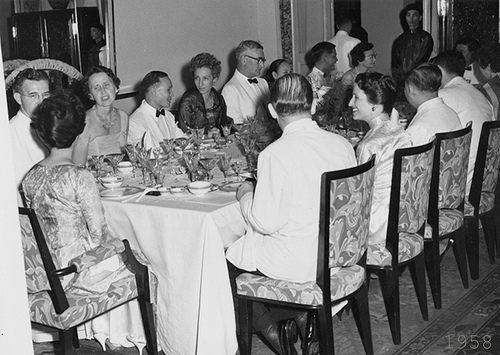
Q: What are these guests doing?
A: Eating dinner.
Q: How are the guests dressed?
A: In formal clothing.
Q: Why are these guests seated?
A: They are eating.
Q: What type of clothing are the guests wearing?
A: Formal clothes.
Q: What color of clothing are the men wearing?
A: White.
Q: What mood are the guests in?
A: Happy.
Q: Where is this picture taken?
A: A dinner party.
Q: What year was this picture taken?
A: 1958.